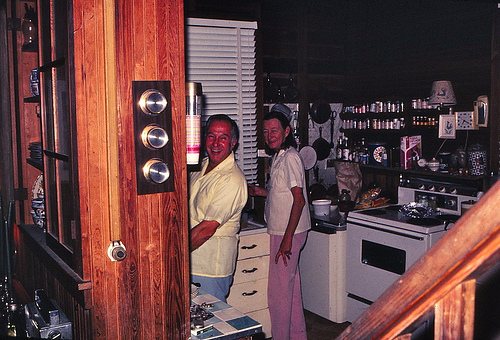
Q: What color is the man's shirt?
A: Yellow.